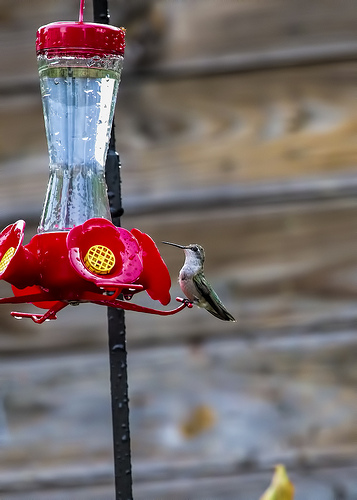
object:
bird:
[160, 238, 236, 321]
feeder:
[2, 3, 195, 318]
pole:
[104, 312, 133, 500]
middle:
[85, 245, 115, 269]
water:
[61, 89, 100, 144]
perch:
[101, 303, 190, 315]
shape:
[66, 219, 142, 287]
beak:
[160, 238, 187, 249]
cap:
[37, 21, 124, 66]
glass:
[37, 61, 117, 221]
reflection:
[91, 84, 108, 171]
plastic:
[39, 62, 122, 233]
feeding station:
[127, 227, 174, 305]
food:
[57, 132, 96, 206]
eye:
[192, 247, 197, 251]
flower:
[67, 216, 148, 292]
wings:
[194, 280, 225, 297]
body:
[178, 267, 211, 304]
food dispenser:
[2, 242, 14, 274]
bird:
[256, 461, 298, 498]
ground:
[6, 443, 342, 486]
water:
[114, 360, 135, 416]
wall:
[156, 54, 314, 196]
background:
[126, 20, 352, 337]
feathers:
[184, 270, 196, 285]